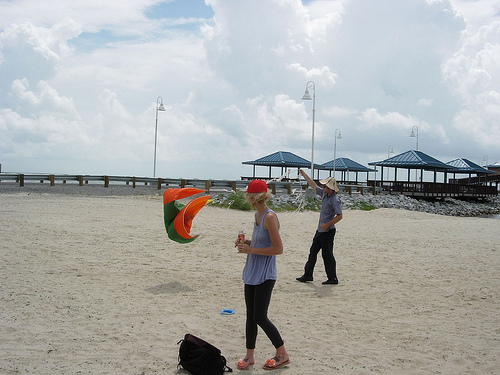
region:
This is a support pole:
[16, 168, 26, 191]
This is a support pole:
[48, 169, 56, 184]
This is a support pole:
[74, 173, 86, 187]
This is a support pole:
[100, 166, 110, 193]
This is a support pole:
[130, 176, 137, 191]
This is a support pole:
[154, 175, 163, 192]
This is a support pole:
[178, 176, 192, 190]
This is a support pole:
[202, 177, 213, 194]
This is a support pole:
[228, 176, 243, 197]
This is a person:
[223, 170, 298, 372]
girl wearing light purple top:
[230, 162, 290, 289]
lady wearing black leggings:
[238, 182, 295, 349]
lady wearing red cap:
[227, 175, 289, 313]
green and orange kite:
[139, 165, 337, 254]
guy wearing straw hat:
[299, 160, 358, 292]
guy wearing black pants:
[292, 159, 352, 289]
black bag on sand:
[156, 318, 236, 373]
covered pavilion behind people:
[232, 129, 495, 269]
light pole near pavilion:
[289, 70, 339, 208]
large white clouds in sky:
[17, 0, 499, 190]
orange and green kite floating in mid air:
[162, 188, 209, 243]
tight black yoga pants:
[243, 279, 283, 349]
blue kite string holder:
[221, 308, 232, 313]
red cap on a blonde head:
[242, 179, 269, 209]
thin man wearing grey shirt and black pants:
[296, 168, 343, 285]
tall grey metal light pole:
[152, 95, 164, 177]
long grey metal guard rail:
[0, 173, 382, 195]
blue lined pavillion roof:
[368, 149, 455, 169]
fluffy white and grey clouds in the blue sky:
[0, 0, 498, 187]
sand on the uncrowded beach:
[0, 192, 499, 374]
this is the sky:
[169, 5, 196, 17]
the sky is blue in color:
[165, 0, 197, 17]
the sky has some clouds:
[251, 15, 468, 111]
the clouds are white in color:
[361, 0, 478, 84]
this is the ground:
[17, 221, 148, 372]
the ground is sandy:
[33, 258, 119, 348]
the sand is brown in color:
[40, 263, 100, 313]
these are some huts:
[238, 145, 489, 189]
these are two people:
[227, 164, 349, 366]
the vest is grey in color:
[244, 260, 263, 279]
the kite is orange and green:
[163, 175, 218, 264]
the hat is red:
[248, 185, 275, 199]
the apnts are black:
[237, 286, 310, 349]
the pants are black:
[298, 225, 346, 288]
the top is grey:
[301, 186, 346, 234]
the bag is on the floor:
[161, 328, 238, 373]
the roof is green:
[271, 143, 376, 168]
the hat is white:
[319, 169, 349, 198]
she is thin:
[224, 175, 322, 351]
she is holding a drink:
[186, 165, 294, 370]